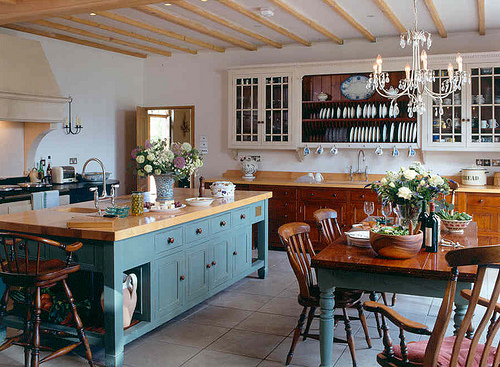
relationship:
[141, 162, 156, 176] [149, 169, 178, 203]
flower in vase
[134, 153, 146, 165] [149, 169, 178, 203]
flower in vase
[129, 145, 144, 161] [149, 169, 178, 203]
flower in vase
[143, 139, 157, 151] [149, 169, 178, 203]
flower in vase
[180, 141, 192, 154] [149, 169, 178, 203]
flower in vase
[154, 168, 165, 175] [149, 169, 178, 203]
flower in vase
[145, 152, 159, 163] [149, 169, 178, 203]
flower in vase